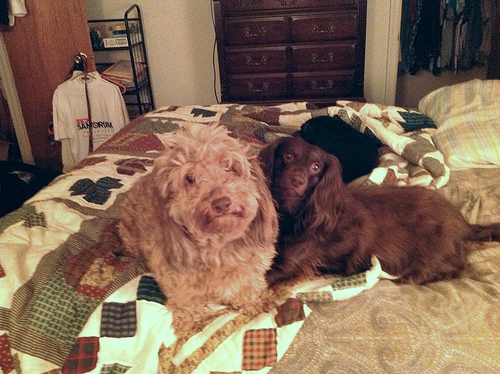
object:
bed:
[3, 100, 498, 370]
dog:
[257, 131, 470, 287]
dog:
[114, 124, 275, 333]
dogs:
[253, 132, 462, 285]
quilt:
[0, 86, 446, 373]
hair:
[256, 136, 473, 286]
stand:
[90, 4, 156, 129]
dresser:
[210, 0, 367, 110]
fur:
[110, 124, 284, 319]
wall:
[83, 0, 224, 112]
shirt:
[54, 68, 132, 175]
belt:
[79, 49, 94, 164]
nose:
[197, 188, 244, 234]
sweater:
[293, 112, 373, 176]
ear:
[298, 140, 342, 239]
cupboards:
[85, 16, 146, 49]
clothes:
[401, 0, 499, 76]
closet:
[386, 2, 496, 112]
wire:
[80, 4, 158, 116]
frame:
[5, 0, 111, 157]